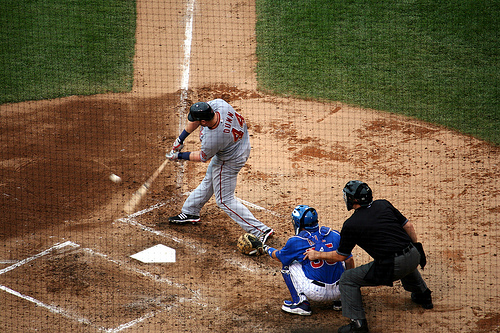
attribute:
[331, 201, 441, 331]
suit — black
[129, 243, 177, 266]
plate — white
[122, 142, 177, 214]
bat — wooden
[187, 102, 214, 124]
helmet — black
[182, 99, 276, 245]
uniform — gray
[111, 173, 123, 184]
ball — in the air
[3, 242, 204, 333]
box — painted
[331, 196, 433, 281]
shirt — black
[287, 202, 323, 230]
helmet — blue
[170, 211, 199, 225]
shoe — black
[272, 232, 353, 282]
shirt — red